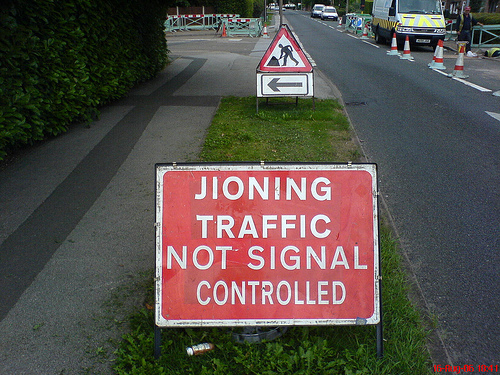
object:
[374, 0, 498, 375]
road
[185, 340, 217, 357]
garbage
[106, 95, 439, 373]
grass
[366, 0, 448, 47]
truck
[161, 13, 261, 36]
fence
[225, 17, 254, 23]
stripes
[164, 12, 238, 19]
stripes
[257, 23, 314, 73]
sign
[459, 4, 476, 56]
person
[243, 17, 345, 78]
corner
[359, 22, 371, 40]
cone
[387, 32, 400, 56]
cone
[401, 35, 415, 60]
cone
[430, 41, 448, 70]
cone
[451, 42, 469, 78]
cone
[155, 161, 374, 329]
sign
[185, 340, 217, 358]
bottle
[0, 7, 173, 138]
bushes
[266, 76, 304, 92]
arrow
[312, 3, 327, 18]
car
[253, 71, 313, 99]
sign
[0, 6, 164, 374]
road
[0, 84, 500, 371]
ground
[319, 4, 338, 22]
car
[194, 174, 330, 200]
word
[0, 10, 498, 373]
street